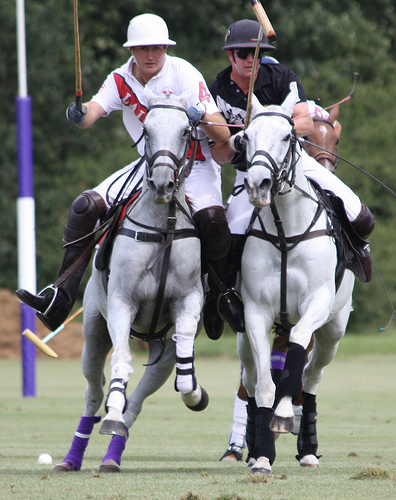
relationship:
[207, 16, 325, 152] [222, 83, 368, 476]
polo player on horse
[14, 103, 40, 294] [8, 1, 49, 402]
indentifying color on pole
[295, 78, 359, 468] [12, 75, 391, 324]
horse in background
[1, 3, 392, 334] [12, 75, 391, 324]
trees are in background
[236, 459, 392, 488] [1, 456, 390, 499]
divets are in ground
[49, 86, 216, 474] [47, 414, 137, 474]
horse has blue wrap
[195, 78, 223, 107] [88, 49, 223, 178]
number 4 on jersey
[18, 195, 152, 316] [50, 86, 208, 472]
crop for horse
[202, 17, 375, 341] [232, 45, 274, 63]
polo player wearing sunglasses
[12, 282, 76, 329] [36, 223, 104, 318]
boot in stirrup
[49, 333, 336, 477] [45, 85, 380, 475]
hooves of horses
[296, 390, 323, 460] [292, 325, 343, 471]
sock on horses leg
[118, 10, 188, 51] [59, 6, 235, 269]
hat on man